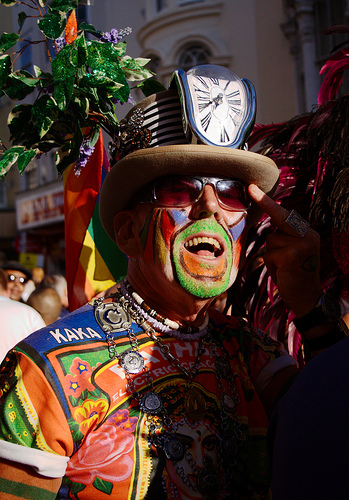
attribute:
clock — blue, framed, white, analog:
[179, 60, 262, 148]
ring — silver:
[287, 210, 311, 240]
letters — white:
[51, 324, 101, 342]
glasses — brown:
[131, 164, 254, 217]